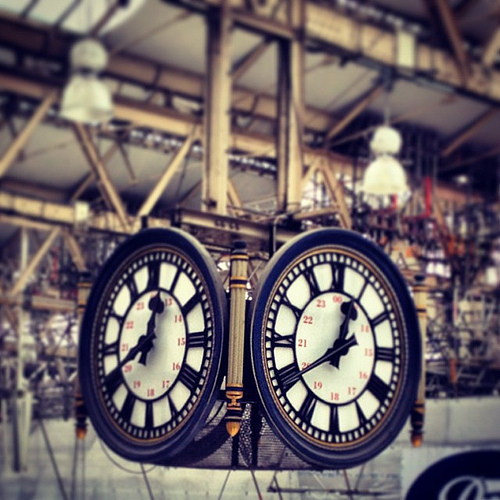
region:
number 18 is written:
[329, 385, 344, 422]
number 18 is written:
[324, 383, 341, 400]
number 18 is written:
[329, 392, 339, 397]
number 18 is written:
[327, 382, 337, 407]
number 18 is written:
[329, 393, 341, 408]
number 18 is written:
[324, 389, 335, 404]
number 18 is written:
[328, 391, 344, 403]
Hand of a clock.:
[100, 281, 173, 389]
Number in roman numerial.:
[279, 250, 396, 433]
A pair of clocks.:
[80, 233, 433, 475]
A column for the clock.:
[225, 237, 247, 450]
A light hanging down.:
[353, 114, 425, 207]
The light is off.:
[60, 35, 120, 131]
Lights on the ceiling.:
[48, 32, 429, 202]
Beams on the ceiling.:
[202, 15, 299, 227]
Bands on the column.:
[222, 251, 250, 288]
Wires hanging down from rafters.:
[22, 446, 163, 498]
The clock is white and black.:
[240, 219, 454, 463]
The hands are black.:
[286, 302, 376, 406]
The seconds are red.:
[279, 278, 393, 443]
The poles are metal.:
[167, 51, 324, 248]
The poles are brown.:
[130, 8, 457, 213]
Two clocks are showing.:
[70, 203, 437, 470]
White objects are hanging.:
[345, 106, 407, 243]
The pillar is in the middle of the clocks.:
[212, 231, 252, 446]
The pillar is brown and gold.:
[183, 226, 260, 483]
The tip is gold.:
[205, 411, 272, 453]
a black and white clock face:
[76, 235, 225, 455]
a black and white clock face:
[259, 222, 408, 462]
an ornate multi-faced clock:
[75, 196, 434, 481]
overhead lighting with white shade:
[364, 124, 406, 199]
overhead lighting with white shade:
[52, 45, 113, 130]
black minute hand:
[289, 336, 351, 385]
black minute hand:
[96, 333, 154, 397]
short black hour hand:
[140, 289, 162, 370]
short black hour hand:
[328, 297, 355, 367]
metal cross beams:
[2, 79, 361, 246]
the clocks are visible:
[108, 250, 298, 412]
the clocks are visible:
[196, 314, 285, 401]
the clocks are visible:
[205, 347, 287, 472]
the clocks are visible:
[166, 305, 324, 492]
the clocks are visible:
[142, 235, 404, 490]